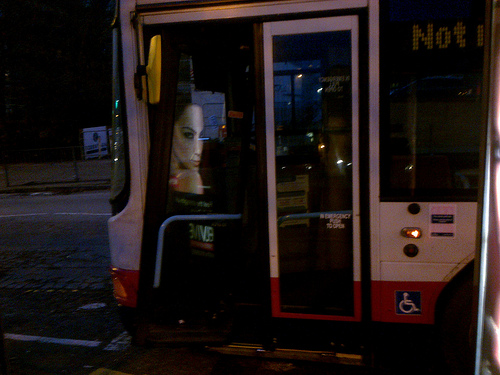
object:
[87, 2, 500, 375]
bus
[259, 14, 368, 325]
door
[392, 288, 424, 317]
sign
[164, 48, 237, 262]
window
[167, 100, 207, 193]
ad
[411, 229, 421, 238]
light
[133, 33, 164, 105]
mirror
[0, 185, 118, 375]
street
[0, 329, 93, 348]
line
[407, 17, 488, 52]
text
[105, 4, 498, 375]
side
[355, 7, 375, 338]
stripe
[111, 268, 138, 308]
reflector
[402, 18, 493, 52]
sign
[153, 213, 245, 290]
rod